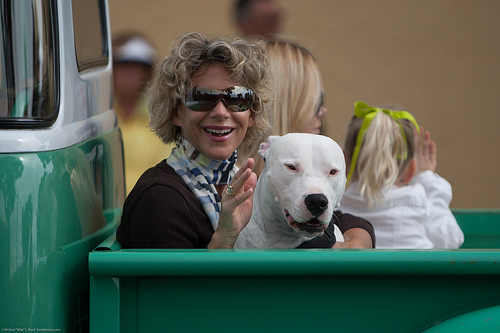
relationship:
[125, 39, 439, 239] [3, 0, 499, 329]
people in a truck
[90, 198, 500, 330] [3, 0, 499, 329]
rear of truck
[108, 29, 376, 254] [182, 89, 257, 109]
people has sunglasses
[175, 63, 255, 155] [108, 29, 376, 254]
face of people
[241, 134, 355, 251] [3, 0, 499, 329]
dog in truck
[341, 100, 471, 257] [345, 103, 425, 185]
girl has ribbons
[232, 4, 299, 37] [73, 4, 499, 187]
man in background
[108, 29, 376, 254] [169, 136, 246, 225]
people has scarf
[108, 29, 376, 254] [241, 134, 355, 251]
people has dog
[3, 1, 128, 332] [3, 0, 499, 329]
cab of truck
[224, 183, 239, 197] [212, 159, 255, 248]
ring on a hand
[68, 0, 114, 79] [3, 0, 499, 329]
back window on truck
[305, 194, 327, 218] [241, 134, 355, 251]
nose on dog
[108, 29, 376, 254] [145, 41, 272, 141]
people has hair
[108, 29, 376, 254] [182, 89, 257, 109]
people with sunglasses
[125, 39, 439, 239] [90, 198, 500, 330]
people in rear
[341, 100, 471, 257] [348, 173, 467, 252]
girl wearing coat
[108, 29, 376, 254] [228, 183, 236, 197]
people wearing a ring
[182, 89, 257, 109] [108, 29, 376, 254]
sunglasses on people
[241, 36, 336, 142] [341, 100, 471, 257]
woman holding girl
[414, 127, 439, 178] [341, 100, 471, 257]
hand of girl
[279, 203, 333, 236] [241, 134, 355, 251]
mouth on a dog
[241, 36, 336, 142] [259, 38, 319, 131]
woman has blonde hair